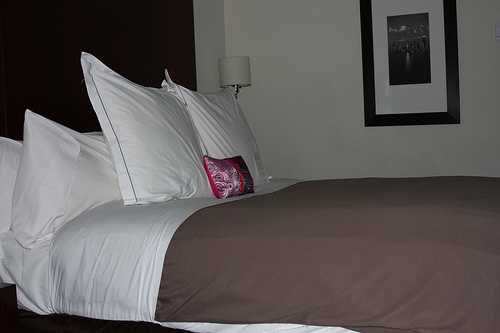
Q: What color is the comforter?
A: Grey.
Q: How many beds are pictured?
A: One.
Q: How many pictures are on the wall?
A: One.